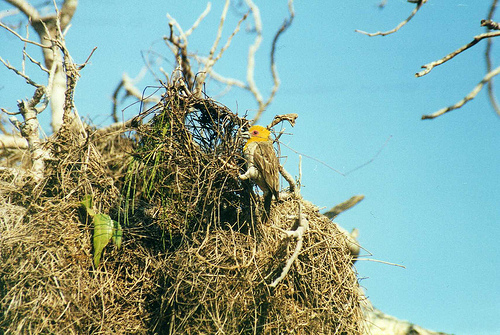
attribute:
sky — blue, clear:
[352, 133, 497, 225]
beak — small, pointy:
[236, 130, 252, 139]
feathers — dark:
[254, 143, 278, 199]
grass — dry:
[1, 139, 366, 333]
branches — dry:
[152, 28, 305, 127]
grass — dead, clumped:
[5, 115, 405, 321]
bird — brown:
[239, 122, 284, 202]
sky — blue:
[0, 1, 499, 331]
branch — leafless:
[420, 65, 498, 120]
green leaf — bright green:
[79, 211, 116, 246]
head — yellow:
[234, 121, 279, 150]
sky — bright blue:
[310, 3, 499, 184]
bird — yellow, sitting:
[233, 123, 305, 208]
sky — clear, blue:
[358, 140, 493, 236]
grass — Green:
[116, 125, 161, 219]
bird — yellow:
[235, 123, 284, 210]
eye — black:
[250, 126, 260, 140]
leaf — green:
[84, 194, 123, 265]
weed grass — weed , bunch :
[1, 60, 368, 333]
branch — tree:
[410, 23, 485, 80]